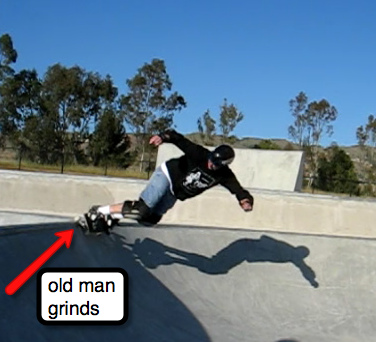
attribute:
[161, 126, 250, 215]
sweatshirt — black